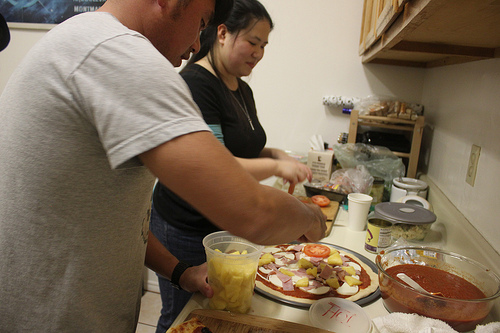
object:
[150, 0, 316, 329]
woman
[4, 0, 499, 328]
kitchen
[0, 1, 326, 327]
man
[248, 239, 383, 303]
pizza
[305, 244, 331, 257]
slice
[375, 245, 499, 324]
bowl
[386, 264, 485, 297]
sauce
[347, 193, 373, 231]
cup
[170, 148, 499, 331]
table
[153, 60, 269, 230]
top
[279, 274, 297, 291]
ham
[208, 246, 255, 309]
cheese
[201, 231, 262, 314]
container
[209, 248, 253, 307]
pineapple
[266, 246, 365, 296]
cheese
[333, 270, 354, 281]
meat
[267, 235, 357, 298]
veggies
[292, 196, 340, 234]
cutting board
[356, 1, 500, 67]
cabinets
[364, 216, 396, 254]
can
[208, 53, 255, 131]
necklace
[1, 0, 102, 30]
picture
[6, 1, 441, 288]
wall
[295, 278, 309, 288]
piece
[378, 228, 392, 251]
label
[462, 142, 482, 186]
switch plate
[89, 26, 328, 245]
arm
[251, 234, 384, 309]
tray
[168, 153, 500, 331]
counter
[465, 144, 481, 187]
outlet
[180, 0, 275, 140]
hair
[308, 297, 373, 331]
lid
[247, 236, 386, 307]
pan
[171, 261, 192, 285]
wrist watch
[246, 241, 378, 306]
food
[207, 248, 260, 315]
food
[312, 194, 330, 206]
slice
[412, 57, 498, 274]
wall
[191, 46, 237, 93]
neck